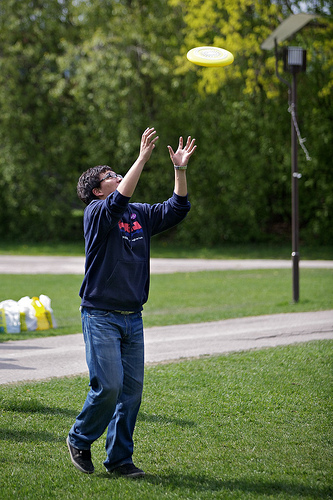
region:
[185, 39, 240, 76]
the frisbee is in the air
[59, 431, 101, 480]
his foot is off the ground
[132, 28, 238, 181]
he is reaching for the frisbee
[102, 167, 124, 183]
he is wearing glasses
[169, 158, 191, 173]
the is wearing something on his wrist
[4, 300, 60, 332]
the bags are on the ground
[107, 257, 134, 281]
the shirt is dark blue in color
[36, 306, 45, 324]
the bag is yellow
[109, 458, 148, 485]
the shoe is on the ground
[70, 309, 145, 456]
the man is wearing denim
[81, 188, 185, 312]
the man is wearing a black top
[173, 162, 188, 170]
the man is wearing a watch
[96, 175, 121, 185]
the man is wearing glasses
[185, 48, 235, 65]
the man is playing frisbee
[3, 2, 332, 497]
the man is outdoors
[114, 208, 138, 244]
the sweater has a design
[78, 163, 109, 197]
the man has short hair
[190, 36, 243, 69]
the man looks at the frisbee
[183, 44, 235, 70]
yellow frisbee in air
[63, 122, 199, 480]
man motioning to catch frisbee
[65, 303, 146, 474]
pair of blue jeans on man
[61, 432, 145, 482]
pair of black sneakers with white soles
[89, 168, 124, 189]
pair of eye glasses on man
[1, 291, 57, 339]
white and yellow bags on green grass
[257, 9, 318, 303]
tall street lamp on grass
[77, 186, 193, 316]
blue sweatshirt on man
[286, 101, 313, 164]
white string hanging down from street lamp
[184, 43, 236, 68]
frisbee flying through midair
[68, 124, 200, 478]
man reaching up into the air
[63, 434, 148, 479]
man wearing black athletic shoes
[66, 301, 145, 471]
man wearing comfy blue jeans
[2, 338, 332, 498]
beautifully manicured lawn next to a street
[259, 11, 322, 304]
light pole set in the grass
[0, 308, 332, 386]
asphalt road bordered by grass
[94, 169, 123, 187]
man is wearing glasses with black frames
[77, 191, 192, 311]
man is wearing a dark sweatshirt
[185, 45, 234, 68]
midair frisbee is yellow in color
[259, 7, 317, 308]
solar powered light on a pole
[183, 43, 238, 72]
yellow frisbie in the air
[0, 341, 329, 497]
green grassy area in a park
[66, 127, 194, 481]
person reaching into the air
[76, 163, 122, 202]
head with short black hair and glasses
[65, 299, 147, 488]
person with sneakers and blue jeans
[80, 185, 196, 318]
dark blue long sleeved shirt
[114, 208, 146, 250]
logo on the front of long sleeved shirt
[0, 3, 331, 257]
trees in the background at a park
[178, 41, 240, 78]
yellow frisbee in the air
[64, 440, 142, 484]
man wearing black shoes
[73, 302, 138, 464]
man wearing blue jeans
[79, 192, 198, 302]
man wearing a blue sweatshirt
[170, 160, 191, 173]
man wearing a silver watch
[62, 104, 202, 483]
man catching a frisbee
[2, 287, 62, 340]
plastic bags on the grass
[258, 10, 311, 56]
solar panel on the pole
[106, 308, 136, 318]
man wearing a belt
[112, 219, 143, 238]
pink writing on the sweatshirt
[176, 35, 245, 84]
yellow Frisbee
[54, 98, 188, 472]
boy catching yellow Frisbee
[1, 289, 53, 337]
yellow and white bags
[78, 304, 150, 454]
blue jeans worn by boy